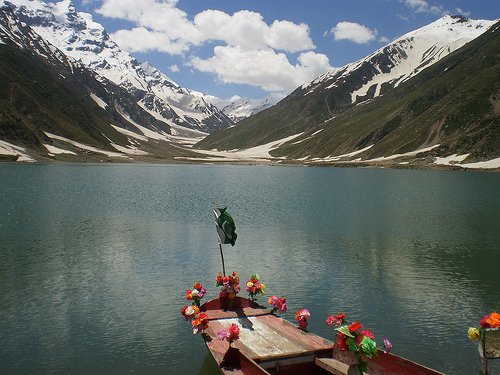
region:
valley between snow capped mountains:
[1, 2, 498, 175]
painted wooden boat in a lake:
[159, 193, 498, 373]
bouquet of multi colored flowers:
[239, 270, 269, 301]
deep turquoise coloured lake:
[3, 152, 496, 373]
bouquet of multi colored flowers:
[319, 308, 396, 373]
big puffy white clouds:
[91, 0, 479, 98]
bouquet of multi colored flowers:
[179, 273, 211, 308]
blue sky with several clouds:
[71, 2, 498, 105]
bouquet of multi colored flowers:
[214, 319, 251, 347]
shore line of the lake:
[1, 153, 498, 175]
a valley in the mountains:
[119, 103, 251, 170]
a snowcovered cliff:
[4, 0, 216, 122]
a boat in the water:
[187, 194, 495, 374]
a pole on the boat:
[208, 202, 228, 283]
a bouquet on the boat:
[185, 283, 209, 310]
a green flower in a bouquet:
[353, 335, 378, 356]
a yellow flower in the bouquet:
[242, 278, 259, 286]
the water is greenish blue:
[3, 149, 493, 372]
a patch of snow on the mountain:
[432, 150, 497, 170]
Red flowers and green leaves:
[325, 310, 377, 360]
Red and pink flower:
[212, 320, 240, 348]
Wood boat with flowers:
[176, 265, 441, 374]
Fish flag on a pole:
[209, 203, 236, 278]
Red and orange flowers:
[479, 308, 499, 330]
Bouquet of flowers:
[242, 270, 264, 306]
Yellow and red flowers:
[242, 272, 265, 302]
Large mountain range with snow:
[0, 0, 498, 175]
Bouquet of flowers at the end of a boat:
[214, 269, 241, 311]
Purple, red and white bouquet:
[182, 280, 207, 302]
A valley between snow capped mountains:
[58, 5, 405, 159]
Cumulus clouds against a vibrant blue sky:
[148, 6, 296, 81]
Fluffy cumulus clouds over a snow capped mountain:
[86, 5, 219, 124]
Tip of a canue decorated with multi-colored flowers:
[187, 198, 407, 372]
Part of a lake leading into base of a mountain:
[257, 11, 493, 233]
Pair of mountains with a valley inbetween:
[11, 3, 491, 161]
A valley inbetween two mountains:
[5, 2, 469, 160]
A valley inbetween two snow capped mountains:
[1, 1, 494, 167]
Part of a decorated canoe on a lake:
[167, 194, 425, 374]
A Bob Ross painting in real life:
[1, 1, 498, 202]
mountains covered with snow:
[2, 0, 495, 82]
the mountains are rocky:
[5, 2, 215, 137]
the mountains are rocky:
[235, 10, 495, 165]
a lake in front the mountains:
[2, 0, 492, 370]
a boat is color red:
[170, 196, 495, 371]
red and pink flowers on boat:
[290, 300, 305, 335]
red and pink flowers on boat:
[215, 320, 245, 350]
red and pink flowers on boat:
[262, 286, 287, 316]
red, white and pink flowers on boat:
[180, 280, 212, 300]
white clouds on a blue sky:
[107, 1, 359, 75]